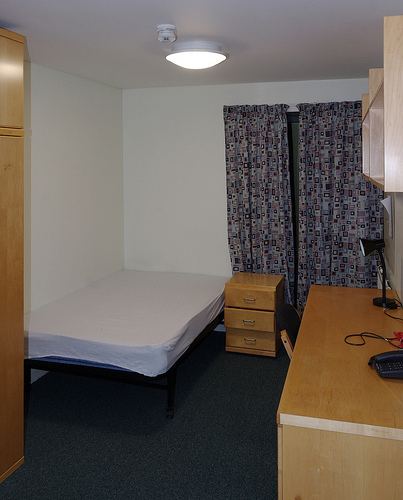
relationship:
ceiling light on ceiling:
[159, 45, 232, 75] [4, 1, 390, 89]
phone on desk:
[366, 348, 390, 375] [275, 282, 388, 484]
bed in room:
[33, 271, 244, 415] [4, 65, 390, 470]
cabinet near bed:
[222, 275, 282, 357] [31, 267, 232, 401]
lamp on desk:
[357, 237, 398, 310] [275, 282, 388, 484]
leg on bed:
[155, 372, 180, 422] [33, 271, 244, 415]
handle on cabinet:
[241, 297, 256, 302] [222, 275, 282, 357]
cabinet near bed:
[222, 275, 282, 357] [33, 271, 244, 415]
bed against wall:
[33, 271, 244, 415] [25, 58, 131, 322]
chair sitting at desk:
[270, 303, 302, 361] [275, 282, 388, 484]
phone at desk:
[366, 348, 390, 375] [276, 281, 390, 469]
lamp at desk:
[357, 237, 398, 310] [275, 282, 388, 484]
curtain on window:
[220, 99, 366, 315] [222, 109, 362, 287]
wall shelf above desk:
[354, 12, 399, 196] [276, 279, 402, 497]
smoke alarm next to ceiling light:
[154, 17, 175, 41] [159, 45, 232, 75]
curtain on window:
[220, 99, 366, 315] [226, 109, 369, 306]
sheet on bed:
[28, 258, 228, 372] [21, 267, 229, 416]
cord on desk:
[343, 319, 384, 347] [276, 279, 402, 497]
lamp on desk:
[357, 237, 398, 310] [276, 279, 402, 497]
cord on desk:
[335, 319, 384, 355] [276, 279, 402, 497]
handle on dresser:
[235, 314, 259, 327] [217, 270, 284, 356]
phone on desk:
[366, 348, 390, 375] [276, 279, 402, 497]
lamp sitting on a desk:
[357, 237, 398, 310] [276, 279, 402, 497]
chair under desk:
[270, 303, 302, 361] [276, 279, 402, 497]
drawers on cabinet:
[222, 304, 277, 331] [222, 275, 282, 357]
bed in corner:
[33, 271, 244, 415] [38, 71, 242, 427]